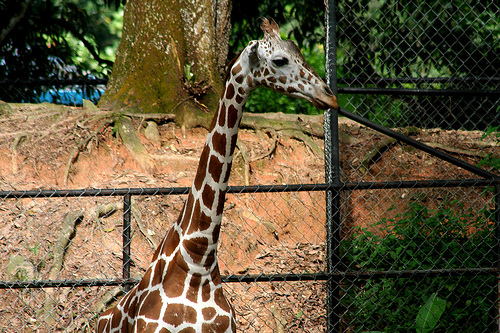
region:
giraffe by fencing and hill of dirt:
[12, 10, 483, 316]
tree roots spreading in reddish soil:
[10, 110, 320, 310]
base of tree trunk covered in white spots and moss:
[100, 2, 230, 122]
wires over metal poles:
[2, 180, 492, 325]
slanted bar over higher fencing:
[325, 5, 495, 325]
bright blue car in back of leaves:
[0, 40, 106, 102]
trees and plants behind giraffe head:
[232, 0, 492, 121]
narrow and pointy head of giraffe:
[246, 15, 336, 110]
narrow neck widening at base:
[150, 55, 255, 261]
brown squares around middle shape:
[215, 62, 246, 128]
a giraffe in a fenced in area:
[39, 32, 491, 303]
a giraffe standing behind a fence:
[66, 33, 363, 325]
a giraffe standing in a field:
[72, 38, 440, 327]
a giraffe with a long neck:
[42, 20, 432, 321]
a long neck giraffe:
[57, 6, 399, 326]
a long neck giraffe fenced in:
[29, 20, 346, 325]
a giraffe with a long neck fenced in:
[32, 5, 392, 327]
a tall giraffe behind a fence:
[57, 16, 427, 326]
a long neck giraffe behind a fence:
[71, 32, 375, 329]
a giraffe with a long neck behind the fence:
[0, 19, 435, 331]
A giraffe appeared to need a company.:
[80, 21, 342, 328]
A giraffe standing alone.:
[89, 18, 341, 332]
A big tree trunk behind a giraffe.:
[75, 0, 225, 115]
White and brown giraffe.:
[88, 8, 343, 329]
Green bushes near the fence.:
[328, 197, 498, 328]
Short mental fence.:
[0, 186, 333, 327]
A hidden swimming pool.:
[7, 65, 104, 105]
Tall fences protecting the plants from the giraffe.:
[322, 2, 497, 330]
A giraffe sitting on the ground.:
[85, 16, 335, 331]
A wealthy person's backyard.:
[0, 2, 497, 332]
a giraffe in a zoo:
[90, 18, 380, 330]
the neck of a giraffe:
[173, 75, 248, 262]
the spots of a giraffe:
[136, 289, 225, 330]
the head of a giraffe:
[235, 12, 343, 114]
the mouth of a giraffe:
[310, 95, 333, 111]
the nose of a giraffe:
[311, 72, 336, 112]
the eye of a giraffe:
[268, 53, 288, 73]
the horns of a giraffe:
[252, 12, 280, 35]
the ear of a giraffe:
[253, 41, 268, 61]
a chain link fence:
[328, 0, 498, 329]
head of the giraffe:
[223, 25, 328, 114]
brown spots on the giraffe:
[128, 273, 215, 327]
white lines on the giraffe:
[156, 225, 219, 297]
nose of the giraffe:
[306, 72, 348, 116]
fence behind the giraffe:
[357, 113, 452, 201]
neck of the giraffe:
[168, 97, 268, 203]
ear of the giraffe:
[236, 33, 273, 63]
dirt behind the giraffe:
[41, 123, 153, 174]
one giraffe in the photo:
[64, 20, 371, 318]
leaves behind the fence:
[351, 233, 478, 328]